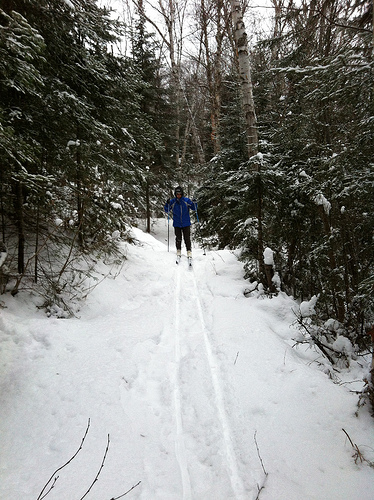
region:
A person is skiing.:
[152, 167, 239, 280]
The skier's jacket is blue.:
[154, 192, 207, 233]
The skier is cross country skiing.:
[152, 172, 221, 295]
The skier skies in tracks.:
[165, 256, 240, 498]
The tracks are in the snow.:
[165, 249, 257, 498]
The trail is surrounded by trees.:
[2, 3, 371, 403]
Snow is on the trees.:
[193, 106, 354, 246]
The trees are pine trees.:
[0, 2, 178, 289]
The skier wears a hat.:
[167, 182, 197, 201]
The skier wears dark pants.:
[167, 218, 201, 253]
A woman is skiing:
[160, 184, 209, 269]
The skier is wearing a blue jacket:
[163, 185, 197, 269]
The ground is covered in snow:
[1, 217, 372, 498]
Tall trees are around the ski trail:
[0, 0, 373, 415]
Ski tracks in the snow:
[163, 269, 245, 498]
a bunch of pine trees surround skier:
[1, 0, 373, 353]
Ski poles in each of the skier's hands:
[164, 199, 207, 258]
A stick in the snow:
[230, 349, 241, 366]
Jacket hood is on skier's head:
[172, 185, 184, 200]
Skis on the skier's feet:
[173, 251, 195, 268]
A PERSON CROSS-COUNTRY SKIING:
[158, 182, 210, 277]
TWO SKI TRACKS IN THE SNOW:
[154, 289, 244, 490]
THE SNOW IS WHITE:
[84, 310, 291, 412]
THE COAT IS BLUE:
[167, 196, 191, 235]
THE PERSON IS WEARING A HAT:
[170, 183, 187, 204]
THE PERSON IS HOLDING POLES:
[162, 199, 211, 257]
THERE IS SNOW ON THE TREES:
[238, 137, 341, 215]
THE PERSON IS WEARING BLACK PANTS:
[171, 223, 193, 251]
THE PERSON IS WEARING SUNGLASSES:
[171, 191, 188, 199]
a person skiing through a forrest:
[2, 11, 364, 490]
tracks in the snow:
[165, 333, 244, 409]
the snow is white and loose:
[12, 330, 118, 424]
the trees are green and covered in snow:
[261, 14, 369, 282]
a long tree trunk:
[226, 14, 264, 151]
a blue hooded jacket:
[166, 177, 193, 230]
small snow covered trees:
[22, 7, 144, 233]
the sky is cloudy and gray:
[183, 19, 200, 53]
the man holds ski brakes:
[190, 199, 211, 264]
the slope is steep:
[212, 262, 293, 433]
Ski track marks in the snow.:
[154, 342, 254, 430]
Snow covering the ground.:
[99, 361, 248, 455]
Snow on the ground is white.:
[75, 345, 209, 464]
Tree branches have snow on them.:
[212, 174, 353, 354]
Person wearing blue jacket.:
[154, 191, 230, 256]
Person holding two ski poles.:
[162, 207, 220, 250]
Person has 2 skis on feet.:
[152, 236, 244, 288]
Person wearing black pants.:
[166, 221, 222, 273]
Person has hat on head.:
[169, 182, 199, 209]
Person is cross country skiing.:
[168, 180, 235, 264]